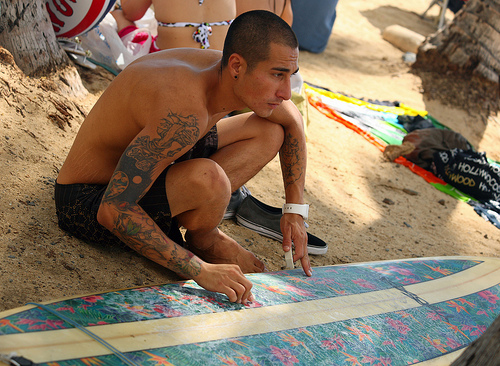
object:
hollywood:
[454, 160, 499, 195]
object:
[417, 146, 498, 203]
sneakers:
[217, 183, 249, 221]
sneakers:
[235, 195, 327, 255]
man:
[51, 10, 313, 304]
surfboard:
[0, 254, 499, 365]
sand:
[0, 239, 86, 298]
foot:
[180, 230, 266, 274]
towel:
[296, 80, 498, 228]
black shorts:
[53, 120, 220, 253]